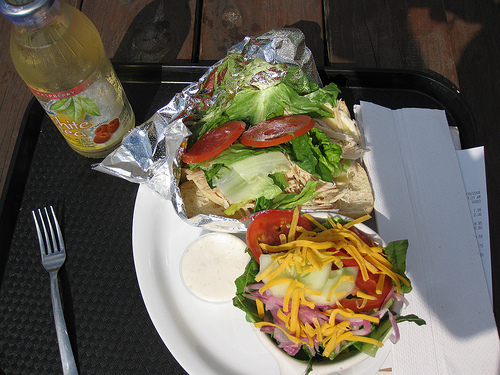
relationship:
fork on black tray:
[29, 205, 80, 374] [1, 58, 498, 373]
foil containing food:
[88, 27, 321, 232] [173, 53, 425, 373]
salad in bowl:
[282, 253, 352, 325] [262, 324, 379, 372]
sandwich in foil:
[176, 28, 373, 218] [93, 25, 375, 234]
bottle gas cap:
[2, 4, 141, 160] [2, 1, 55, 22]